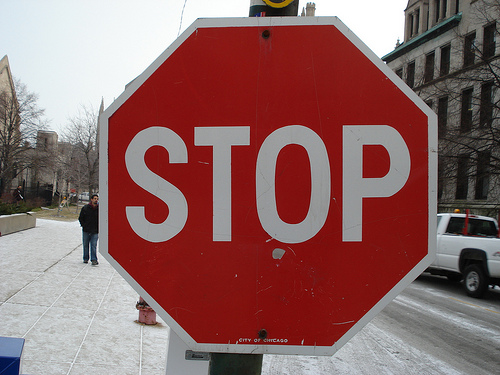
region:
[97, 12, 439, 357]
Stop sign is a hexagon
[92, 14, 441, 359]
Stop sign is red and white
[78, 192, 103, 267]
Man is walking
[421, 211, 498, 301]
White truck is parked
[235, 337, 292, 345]
CITY OF CHICAGO written on stop sign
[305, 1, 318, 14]
Tower of building seen behind stop sign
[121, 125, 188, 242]
Letter S is white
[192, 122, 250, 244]
Letter T in stop sign is white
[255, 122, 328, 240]
Letter O in stop sign is white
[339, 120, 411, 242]
Letter P in stop sign is white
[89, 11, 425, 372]
A stop sign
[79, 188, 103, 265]
A man standing in the background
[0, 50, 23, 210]
Part of a building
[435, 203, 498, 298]
Part of a white van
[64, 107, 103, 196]
A tree with no leaves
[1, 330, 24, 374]
The corner of a blue structure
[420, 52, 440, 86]
A window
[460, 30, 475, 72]
A window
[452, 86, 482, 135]
A window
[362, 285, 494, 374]
Part of a the street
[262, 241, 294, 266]
a chip of red paint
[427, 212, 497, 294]
white pick-up truck on the right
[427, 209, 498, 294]
white truck on the right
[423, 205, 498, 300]
truck parked on the right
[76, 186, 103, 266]
man walking on sidewalk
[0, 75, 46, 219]
tree without leaves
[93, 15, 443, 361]
bright red and white sign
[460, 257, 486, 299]
rear tire of truck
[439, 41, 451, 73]
third story window of building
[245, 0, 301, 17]
top of sign post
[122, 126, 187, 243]
white letter S on sign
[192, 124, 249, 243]
white letter T on sign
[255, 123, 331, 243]
white letter O on sign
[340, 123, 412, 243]
white letter P on sign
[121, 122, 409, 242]
white word STOP on sign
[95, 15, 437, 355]
red and white octagon sign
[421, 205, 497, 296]
parked white work truck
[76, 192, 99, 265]
man in black jacket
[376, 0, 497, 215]
multi-story building on right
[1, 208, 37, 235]
short concrete wall on left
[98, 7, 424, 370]
red stop sign with white text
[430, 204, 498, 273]
white pick up truck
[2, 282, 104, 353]
stone tiles on sidewalk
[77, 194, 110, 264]
man wearing black jacket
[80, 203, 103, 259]
man wearing blue jeans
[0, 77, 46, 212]
trees with no leaves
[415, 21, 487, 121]
tan building with windows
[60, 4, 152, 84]
blue sky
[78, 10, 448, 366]
hexagon shaped stop sign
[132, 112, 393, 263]
stop in white text